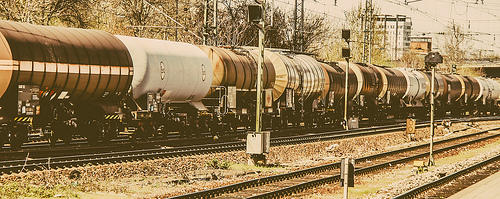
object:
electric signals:
[205, 3, 477, 121]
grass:
[0, 121, 479, 199]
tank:
[111, 31, 215, 113]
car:
[0, 20, 500, 156]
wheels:
[0, 99, 497, 152]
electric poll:
[335, 28, 355, 140]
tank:
[0, 18, 130, 102]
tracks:
[0, 105, 500, 199]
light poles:
[425, 52, 446, 168]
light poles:
[342, 43, 350, 130]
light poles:
[246, 5, 270, 166]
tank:
[198, 45, 264, 100]